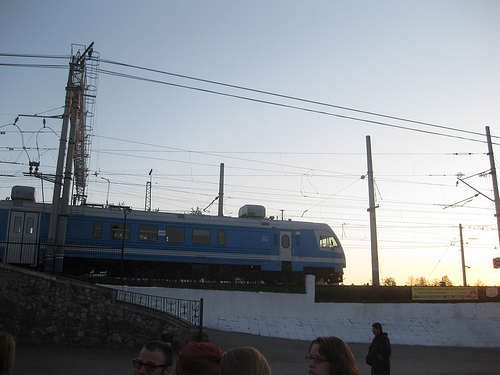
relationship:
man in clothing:
[365, 320, 392, 373] [366, 331, 391, 369]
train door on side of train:
[7, 209, 42, 264] [31, 180, 363, 287]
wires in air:
[4, 47, 498, 265] [0, 0, 499, 375]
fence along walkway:
[117, 288, 204, 336] [14, 322, 498, 372]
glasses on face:
[303, 353, 324, 364] [138, 354, 160, 372]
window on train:
[192, 227, 212, 246] [0, 186, 346, 285]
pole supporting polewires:
[345, 170, 396, 264] [368, 110, 458, 265]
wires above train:
[98, 93, 482, 240] [10, 196, 320, 283]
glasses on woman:
[303, 353, 324, 364] [302, 332, 361, 374]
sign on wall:
[411, 287, 479, 301] [95, 280, 498, 350]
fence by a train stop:
[119, 287, 211, 337] [0, 273, 204, 371]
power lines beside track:
[309, 91, 387, 141] [104, 273, 479, 303]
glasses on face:
[305, 355, 327, 366] [303, 314, 348, 373]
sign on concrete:
[411, 287, 479, 301] [314, 285, 484, 303]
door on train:
[278, 228, 293, 261] [52, 178, 386, 290]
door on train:
[278, 228, 293, 261] [0, 183, 350, 293]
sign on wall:
[411, 287, 479, 301] [364, 126, 416, 304]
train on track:
[0, 186, 346, 285] [104, 273, 482, 308]